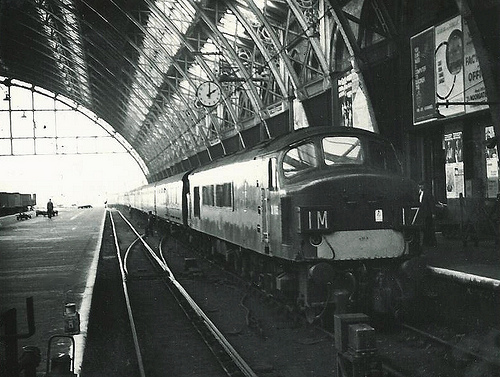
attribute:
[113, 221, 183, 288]
tracks — merging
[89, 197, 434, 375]
train tracks — parallel